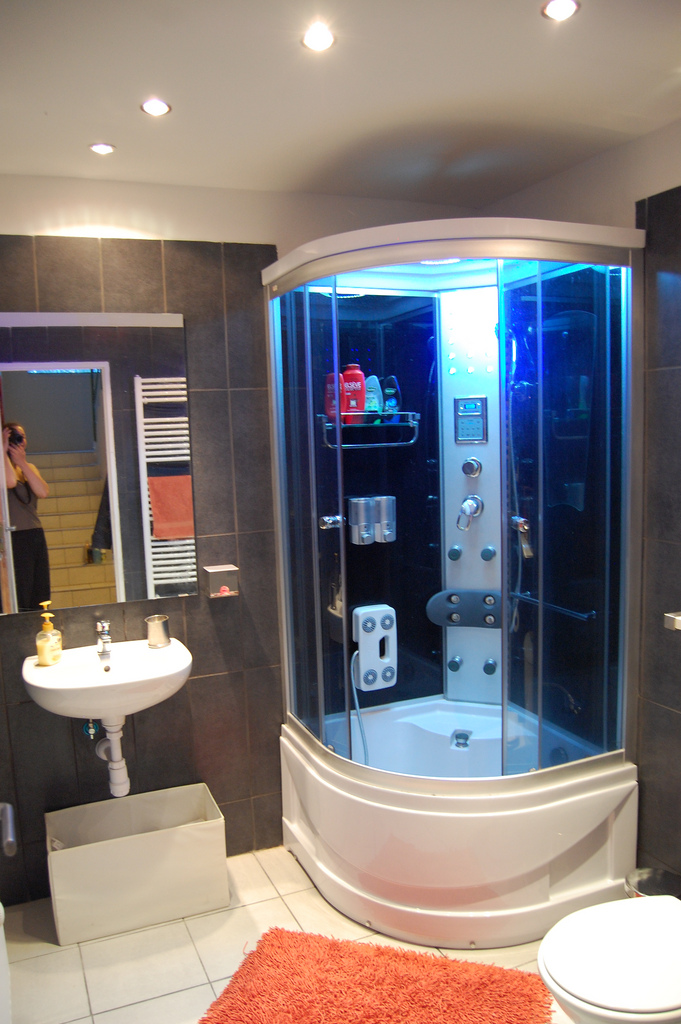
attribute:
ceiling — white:
[164, 99, 295, 158]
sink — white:
[18, 631, 135, 718]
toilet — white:
[528, 905, 669, 975]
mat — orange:
[199, 933, 470, 1020]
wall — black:
[195, 726, 245, 760]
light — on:
[407, 309, 560, 403]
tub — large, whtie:
[29, 797, 213, 913]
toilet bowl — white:
[523, 959, 649, 1014]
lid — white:
[598, 938, 677, 985]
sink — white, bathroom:
[17, 627, 202, 805]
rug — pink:
[185, 921, 552, 1023]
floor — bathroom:
[5, 849, 677, 1021]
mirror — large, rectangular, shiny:
[3, 360, 129, 627]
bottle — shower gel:
[339, 359, 368, 427]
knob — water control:
[459, 456, 483, 480]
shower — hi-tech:
[248, 217, 651, 952]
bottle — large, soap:
[31, 607, 68, 670]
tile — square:
[72, 913, 213, 1015]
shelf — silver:
[315, 408, 419, 456]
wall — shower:
[276, 278, 455, 729]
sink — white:
[17, 630, 199, 819]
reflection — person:
[3, 423, 57, 618]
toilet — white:
[533, 884, 679, 1023]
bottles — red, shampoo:
[333, 355, 366, 418]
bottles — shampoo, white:
[359, 370, 388, 430]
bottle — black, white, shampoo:
[378, 375, 406, 427]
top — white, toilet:
[541, 887, 678, 1019]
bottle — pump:
[29, 609, 62, 667]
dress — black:
[3, 464, 58, 612]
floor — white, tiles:
[5, 846, 532, 1015]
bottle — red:
[335, 357, 370, 423]